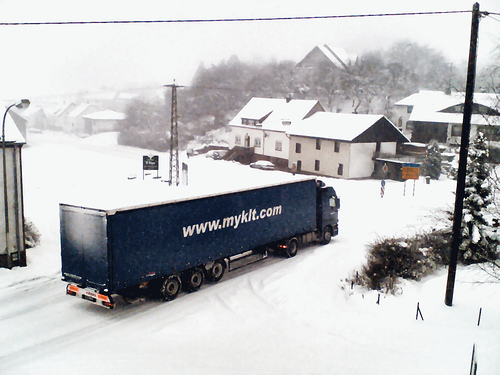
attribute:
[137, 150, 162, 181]
sign — black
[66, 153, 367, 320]
truck — big, semi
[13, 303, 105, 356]
road — snow covered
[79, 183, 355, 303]
truck — dark blue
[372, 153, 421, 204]
sign — red, white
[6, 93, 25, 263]
street light — tall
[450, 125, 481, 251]
pine tree — tall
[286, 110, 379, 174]
building — white, simple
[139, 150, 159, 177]
sign — Dark colored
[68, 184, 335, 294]
truck — dark blue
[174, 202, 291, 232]
words — white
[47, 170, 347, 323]
truck — large, semi truck, driving, huge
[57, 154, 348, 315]
truck — long, Blue, semi, driving, large semi truck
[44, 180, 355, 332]
truck — full size, driving